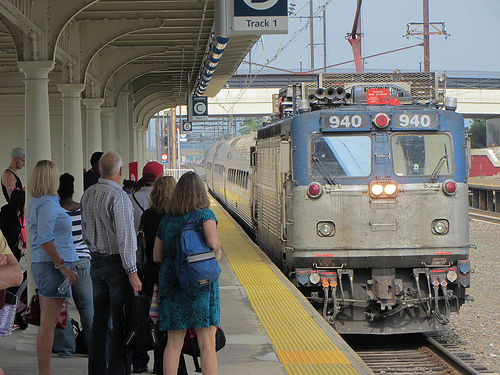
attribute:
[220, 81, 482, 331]
train — arriving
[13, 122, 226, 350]
people — waiting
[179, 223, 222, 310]
bag — blue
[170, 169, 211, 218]
hair — brown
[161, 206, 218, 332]
dress — green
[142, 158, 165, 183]
cap — red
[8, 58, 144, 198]
columns — white